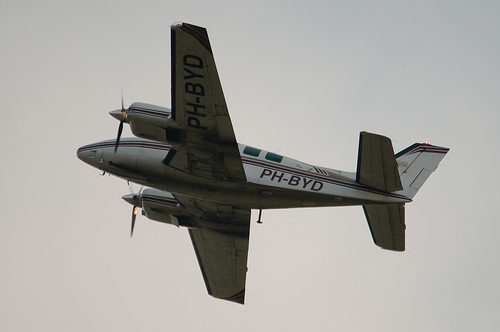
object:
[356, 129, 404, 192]
wing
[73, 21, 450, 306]
plane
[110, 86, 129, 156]
propeller engine